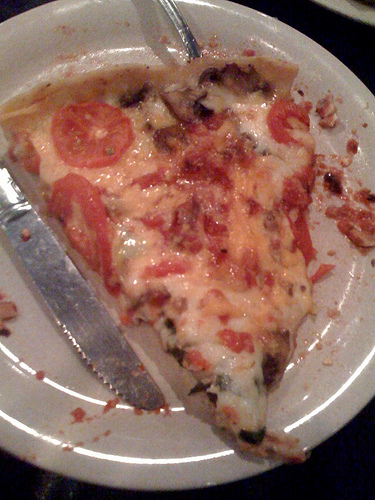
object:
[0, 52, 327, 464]
pizza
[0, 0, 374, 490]
plate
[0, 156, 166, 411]
knife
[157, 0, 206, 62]
fork